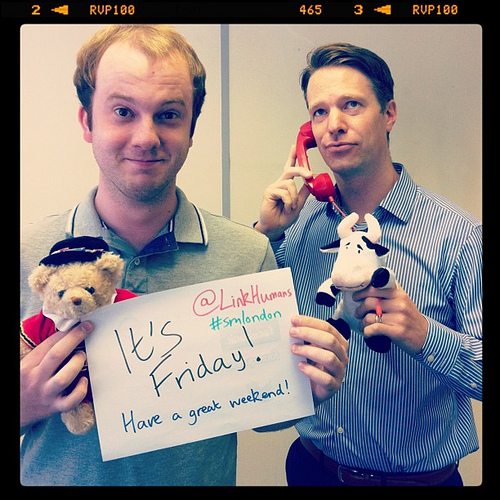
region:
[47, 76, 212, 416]
man holding bear and sign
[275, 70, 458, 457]
man holding phone and cow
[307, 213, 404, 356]
stuffed cow with horns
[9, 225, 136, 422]
bear in beefeater costume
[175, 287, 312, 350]
sign with twitter tags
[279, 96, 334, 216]
red toy phone receiver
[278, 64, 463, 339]
man wearing striped shirt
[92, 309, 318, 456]
man holding handwritten sign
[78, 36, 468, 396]
two men posing for twitter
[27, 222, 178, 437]
stuffed bear from England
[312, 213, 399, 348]
black and white toy cow in man's hand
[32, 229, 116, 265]
Black cap on teddy bear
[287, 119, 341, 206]
red phone in man's hand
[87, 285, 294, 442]
Sign with colorful words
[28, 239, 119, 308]
teddy bear with brown nose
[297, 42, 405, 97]
brown hair on man with blue shirt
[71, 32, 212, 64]
blonde hair on man's head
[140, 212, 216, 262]
collar of man's shirt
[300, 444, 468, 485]
belt on man's pants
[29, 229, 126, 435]
man holding teddy bear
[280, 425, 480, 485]
a man's beltline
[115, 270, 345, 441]
Sign held by a left hand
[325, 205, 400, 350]
stuffed black and white cow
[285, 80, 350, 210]
man on the telephone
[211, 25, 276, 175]
an office's wall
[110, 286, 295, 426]
message to the internet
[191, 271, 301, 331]
a twitter account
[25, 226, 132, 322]
a teddy bear with red jacket and black cap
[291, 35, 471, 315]
man holds a stuffed animal while on the phone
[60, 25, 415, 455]
office workers attempt to go viral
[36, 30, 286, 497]
the man holding a teddy bear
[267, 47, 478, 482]
the man holding a stuffed cow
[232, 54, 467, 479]
the man holding a telephone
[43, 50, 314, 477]
the man holding a sign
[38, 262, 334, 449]
the sign is paper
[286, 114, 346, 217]
the phone is red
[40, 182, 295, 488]
the man wearing a polo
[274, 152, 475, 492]
the man wearing a shirt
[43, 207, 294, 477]
the polo is gray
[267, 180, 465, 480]
the shirt is striped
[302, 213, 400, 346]
stuffed cow in man's hand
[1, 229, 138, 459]
teddy bear in man's hand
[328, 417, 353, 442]
button on man's shirt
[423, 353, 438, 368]
button on man's shirt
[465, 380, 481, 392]
button on man's shirt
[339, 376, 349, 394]
button on man's shirt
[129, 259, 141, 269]
button on man's shirt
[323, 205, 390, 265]
horns on stuffed cow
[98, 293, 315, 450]
sign in man's hand